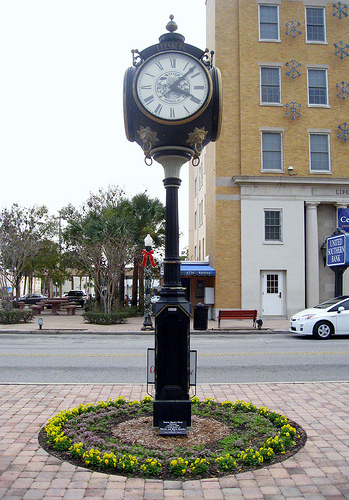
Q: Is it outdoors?
A: Yes, it is outdoors.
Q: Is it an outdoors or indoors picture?
A: It is outdoors.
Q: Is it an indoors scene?
A: No, it is outdoors.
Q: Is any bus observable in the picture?
A: No, there are no buses.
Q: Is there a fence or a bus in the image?
A: No, there are no buses or fences.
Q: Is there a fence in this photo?
A: No, there are no fences.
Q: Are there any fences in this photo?
A: No, there are no fences.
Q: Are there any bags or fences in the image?
A: No, there are no fences or bags.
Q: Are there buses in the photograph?
A: No, there are no buses.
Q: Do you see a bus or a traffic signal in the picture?
A: No, there are no buses or traffic lights.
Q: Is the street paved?
A: Yes, the street is paved.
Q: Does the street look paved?
A: Yes, the street is paved.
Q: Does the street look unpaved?
A: No, the street is paved.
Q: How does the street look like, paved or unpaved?
A: The street is paved.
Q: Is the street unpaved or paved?
A: The street is paved.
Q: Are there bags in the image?
A: No, there are no bags.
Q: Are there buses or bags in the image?
A: No, there are no bags or buses.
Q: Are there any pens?
A: No, there are no pens.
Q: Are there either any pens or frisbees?
A: No, there are no pens or frisbees.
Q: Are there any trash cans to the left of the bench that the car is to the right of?
A: Yes, there is a trash can to the left of the bench.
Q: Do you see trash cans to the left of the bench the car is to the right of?
A: Yes, there is a trash can to the left of the bench.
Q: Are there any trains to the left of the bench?
A: No, there is a trash can to the left of the bench.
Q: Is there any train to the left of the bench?
A: No, there is a trash can to the left of the bench.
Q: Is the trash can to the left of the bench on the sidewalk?
A: Yes, the trash can is to the left of the bench.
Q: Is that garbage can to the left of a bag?
A: No, the garbage can is to the left of the bench.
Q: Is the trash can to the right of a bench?
A: No, the trash can is to the left of a bench.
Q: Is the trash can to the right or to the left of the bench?
A: The trash can is to the left of the bench.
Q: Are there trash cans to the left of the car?
A: Yes, there is a trash can to the left of the car.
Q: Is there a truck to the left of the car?
A: No, there is a trash can to the left of the car.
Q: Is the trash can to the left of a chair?
A: No, the trash can is to the left of the car.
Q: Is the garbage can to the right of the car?
A: No, the garbage can is to the left of the car.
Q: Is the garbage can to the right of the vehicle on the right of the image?
A: No, the garbage can is to the left of the car.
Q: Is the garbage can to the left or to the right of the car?
A: The garbage can is to the left of the car.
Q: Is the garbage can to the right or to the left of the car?
A: The garbage can is to the left of the car.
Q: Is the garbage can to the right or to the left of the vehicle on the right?
A: The garbage can is to the left of the car.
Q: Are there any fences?
A: No, there are no fences.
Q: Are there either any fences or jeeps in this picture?
A: No, there are no fences or jeeps.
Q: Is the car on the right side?
A: Yes, the car is on the right of the image.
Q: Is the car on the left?
A: No, the car is on the right of the image.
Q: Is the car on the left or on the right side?
A: The car is on the right of the image.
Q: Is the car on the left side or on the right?
A: The car is on the right of the image.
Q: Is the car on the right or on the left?
A: The car is on the right of the image.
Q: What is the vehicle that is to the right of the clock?
A: The vehicle is a car.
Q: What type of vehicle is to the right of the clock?
A: The vehicle is a car.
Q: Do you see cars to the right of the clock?
A: Yes, there is a car to the right of the clock.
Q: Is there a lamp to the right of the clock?
A: No, there is a car to the right of the clock.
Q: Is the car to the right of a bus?
A: No, the car is to the right of a clock.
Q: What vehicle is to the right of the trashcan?
A: The vehicle is a car.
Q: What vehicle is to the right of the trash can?
A: The vehicle is a car.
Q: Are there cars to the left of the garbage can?
A: No, the car is to the right of the garbage can.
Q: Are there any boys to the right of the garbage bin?
A: No, there is a car to the right of the garbage bin.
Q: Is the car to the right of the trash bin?
A: Yes, the car is to the right of the trash bin.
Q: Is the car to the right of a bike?
A: No, the car is to the right of the trash bin.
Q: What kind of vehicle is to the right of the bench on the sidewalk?
A: The vehicle is a car.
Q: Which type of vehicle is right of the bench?
A: The vehicle is a car.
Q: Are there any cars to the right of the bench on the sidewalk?
A: Yes, there is a car to the right of the bench.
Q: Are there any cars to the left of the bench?
A: No, the car is to the right of the bench.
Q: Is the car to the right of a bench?
A: Yes, the car is to the right of a bench.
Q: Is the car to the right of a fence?
A: No, the car is to the right of a bench.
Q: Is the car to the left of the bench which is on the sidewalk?
A: No, the car is to the right of the bench.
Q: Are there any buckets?
A: No, there are no buckets.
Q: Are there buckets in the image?
A: No, there are no buckets.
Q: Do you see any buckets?
A: No, there are no buckets.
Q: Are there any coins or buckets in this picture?
A: No, there are no buckets or coins.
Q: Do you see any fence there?
A: No, there are no fences.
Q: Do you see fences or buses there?
A: No, there are no fences or buses.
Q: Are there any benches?
A: Yes, there is a bench.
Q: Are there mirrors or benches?
A: Yes, there is a bench.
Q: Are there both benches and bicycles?
A: No, there is a bench but no bikes.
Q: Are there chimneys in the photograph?
A: No, there are no chimneys.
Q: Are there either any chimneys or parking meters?
A: No, there are no chimneys or parking meters.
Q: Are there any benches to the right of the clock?
A: Yes, there is a bench to the right of the clock.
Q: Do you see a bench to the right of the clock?
A: Yes, there is a bench to the right of the clock.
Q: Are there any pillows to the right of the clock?
A: No, there is a bench to the right of the clock.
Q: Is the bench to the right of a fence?
A: No, the bench is to the right of the clock.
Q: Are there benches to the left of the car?
A: Yes, there is a bench to the left of the car.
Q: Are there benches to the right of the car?
A: No, the bench is to the left of the car.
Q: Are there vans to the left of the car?
A: No, there is a bench to the left of the car.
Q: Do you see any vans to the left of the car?
A: No, there is a bench to the left of the car.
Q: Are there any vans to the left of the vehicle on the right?
A: No, there is a bench to the left of the car.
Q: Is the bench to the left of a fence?
A: No, the bench is to the left of a car.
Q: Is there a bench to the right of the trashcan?
A: Yes, there is a bench to the right of the trashcan.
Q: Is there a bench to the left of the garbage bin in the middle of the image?
A: No, the bench is to the right of the garbage bin.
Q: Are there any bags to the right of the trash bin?
A: No, there is a bench to the right of the trash bin.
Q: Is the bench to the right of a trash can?
A: Yes, the bench is to the right of a trash can.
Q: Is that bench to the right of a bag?
A: No, the bench is to the right of a trash can.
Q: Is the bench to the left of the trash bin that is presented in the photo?
A: No, the bench is to the right of the trash bin.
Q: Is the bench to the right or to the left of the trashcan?
A: The bench is to the right of the trashcan.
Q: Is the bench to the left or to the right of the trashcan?
A: The bench is to the right of the trashcan.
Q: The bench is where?
A: The bench is on the sidewalk.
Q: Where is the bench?
A: The bench is on the sidewalk.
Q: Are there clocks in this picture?
A: Yes, there is a clock.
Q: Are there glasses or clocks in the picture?
A: Yes, there is a clock.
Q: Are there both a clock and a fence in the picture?
A: No, there is a clock but no fences.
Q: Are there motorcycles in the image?
A: No, there are no motorcycles.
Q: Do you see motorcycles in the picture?
A: No, there are no motorcycles.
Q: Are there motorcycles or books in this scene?
A: No, there are no motorcycles or books.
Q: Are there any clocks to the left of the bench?
A: Yes, there is a clock to the left of the bench.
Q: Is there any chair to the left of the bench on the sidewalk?
A: No, there is a clock to the left of the bench.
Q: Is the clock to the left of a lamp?
A: No, the clock is to the left of the bench.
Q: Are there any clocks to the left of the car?
A: Yes, there is a clock to the left of the car.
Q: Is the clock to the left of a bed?
A: No, the clock is to the left of the car.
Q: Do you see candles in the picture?
A: No, there are no candles.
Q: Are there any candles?
A: No, there are no candles.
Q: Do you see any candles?
A: No, there are no candles.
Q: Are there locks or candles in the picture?
A: No, there are no candles or locks.